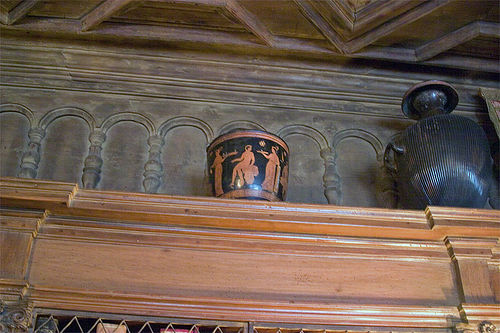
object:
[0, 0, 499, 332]
scene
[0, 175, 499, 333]
wood